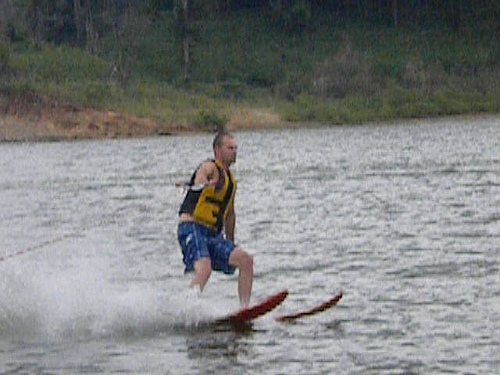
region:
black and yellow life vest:
[178, 162, 240, 239]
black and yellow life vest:
[169, 147, 259, 225]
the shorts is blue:
[172, 222, 259, 272]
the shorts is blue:
[150, 213, 267, 295]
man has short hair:
[212, 124, 239, 154]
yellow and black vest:
[162, 155, 241, 234]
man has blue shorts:
[165, 226, 246, 275]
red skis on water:
[202, 275, 329, 341]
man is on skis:
[155, 195, 334, 336]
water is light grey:
[292, 199, 451, 311]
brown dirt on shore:
[84, 97, 284, 143]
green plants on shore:
[271, 87, 445, 128]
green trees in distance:
[150, 3, 389, 70]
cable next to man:
[0, 174, 243, 249]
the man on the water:
[175, 132, 253, 309]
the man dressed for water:
[177, 130, 252, 306]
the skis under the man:
[200, 289, 345, 318]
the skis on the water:
[203, 289, 342, 322]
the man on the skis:
[176, 133, 256, 310]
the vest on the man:
[179, 157, 236, 229]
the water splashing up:
[1, 243, 248, 340]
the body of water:
[0, 113, 499, 374]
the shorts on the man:
[176, 220, 236, 273]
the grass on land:
[0, 0, 497, 131]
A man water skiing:
[150, 113, 352, 333]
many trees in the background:
[44, 15, 379, 77]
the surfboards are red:
[200, 290, 340, 322]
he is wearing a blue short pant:
[180, 222, 235, 278]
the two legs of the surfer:
[176, 222, 252, 313]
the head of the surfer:
[212, 133, 237, 165]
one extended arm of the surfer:
[191, 160, 216, 195]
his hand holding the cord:
[176, 176, 217, 191]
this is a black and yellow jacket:
[182, 160, 235, 224]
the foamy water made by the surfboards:
[18, 272, 225, 334]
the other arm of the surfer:
[225, 187, 235, 239]